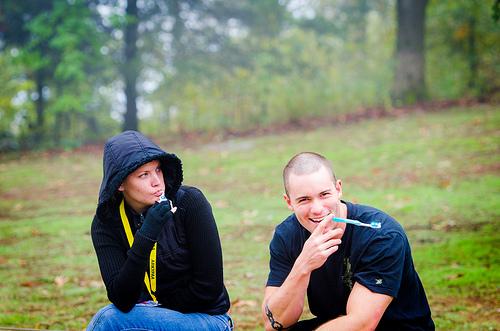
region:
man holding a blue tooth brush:
[259, 150, 439, 330]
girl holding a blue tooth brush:
[80, 128, 235, 328]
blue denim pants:
[77, 297, 244, 329]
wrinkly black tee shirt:
[260, 199, 436, 329]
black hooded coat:
[87, 126, 228, 313]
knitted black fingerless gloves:
[132, 193, 177, 235]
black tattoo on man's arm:
[255, 295, 288, 328]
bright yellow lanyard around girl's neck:
[113, 193, 158, 306]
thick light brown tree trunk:
[390, 2, 430, 111]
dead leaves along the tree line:
[2, 90, 498, 167]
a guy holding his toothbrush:
[252, 149, 432, 329]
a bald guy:
[253, 148, 438, 328]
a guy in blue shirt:
[259, 148, 436, 329]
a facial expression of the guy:
[290, 185, 342, 237]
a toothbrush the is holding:
[326, 213, 382, 230]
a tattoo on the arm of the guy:
[264, 304, 283, 329]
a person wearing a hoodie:
[76, 128, 233, 329]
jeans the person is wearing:
[83, 300, 235, 328]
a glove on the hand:
[138, 199, 175, 241]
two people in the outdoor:
[81, 127, 441, 329]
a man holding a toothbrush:
[273, 150, 424, 246]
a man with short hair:
[247, 143, 343, 208]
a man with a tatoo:
[256, 294, 286, 329]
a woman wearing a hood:
[87, 120, 181, 203]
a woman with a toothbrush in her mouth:
[150, 179, 177, 221]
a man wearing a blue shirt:
[273, 187, 398, 278]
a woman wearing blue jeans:
[107, 310, 217, 329]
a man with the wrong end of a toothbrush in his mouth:
[317, 209, 347, 247]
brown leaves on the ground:
[241, 61, 472, 146]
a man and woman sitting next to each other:
[77, 141, 447, 316]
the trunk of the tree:
[394, 5, 431, 108]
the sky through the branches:
[110, 8, 189, 63]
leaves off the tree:
[44, 15, 94, 97]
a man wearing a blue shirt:
[267, 162, 402, 324]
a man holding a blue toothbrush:
[260, 150, 415, 323]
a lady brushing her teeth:
[78, 130, 224, 325]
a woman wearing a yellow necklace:
[96, 144, 223, 324]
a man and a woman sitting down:
[79, 135, 414, 328]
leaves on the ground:
[257, 117, 490, 147]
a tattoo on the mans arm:
[263, 294, 280, 328]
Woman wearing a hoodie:
[88, 130, 188, 207]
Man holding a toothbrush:
[279, 148, 389, 270]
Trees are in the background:
[1, 1, 497, 147]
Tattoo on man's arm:
[259, 290, 289, 330]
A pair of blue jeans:
[84, 298, 235, 329]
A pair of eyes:
[293, 186, 333, 206]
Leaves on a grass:
[2, 91, 497, 328]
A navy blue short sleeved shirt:
[261, 198, 440, 329]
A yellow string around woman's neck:
[115, 193, 161, 307]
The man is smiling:
[277, 150, 348, 238]